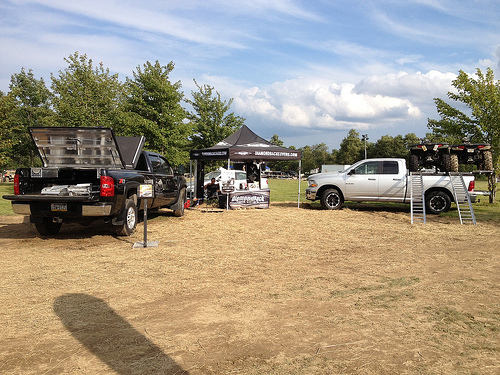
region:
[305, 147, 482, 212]
Silver four wheeled pick up truck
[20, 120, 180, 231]
Black pick up truck parked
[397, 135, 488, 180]
Two four wheeler ATVs in bed of a pickup truck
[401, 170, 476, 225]
Two ladders leaning against silver truck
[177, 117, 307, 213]
Black and white tent over a table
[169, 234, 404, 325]
Patchy brown dirt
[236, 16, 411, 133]
Pale blue sky with large clouds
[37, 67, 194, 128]
Stand of green trees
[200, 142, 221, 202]
Man sitting down under tent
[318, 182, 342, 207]
Wheel of a truck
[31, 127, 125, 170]
Open bed of truck.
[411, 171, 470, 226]
A ramp for the truck.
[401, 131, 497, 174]
A pair of ATVs.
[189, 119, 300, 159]
The black tent roof.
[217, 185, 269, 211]
A booth with advertisements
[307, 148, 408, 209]
The cab of a truck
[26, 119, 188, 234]
A black ford truck.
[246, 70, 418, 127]
The clouds in the sky.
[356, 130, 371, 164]
A light in the distance.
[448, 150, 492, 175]
Wheels covered in dirt.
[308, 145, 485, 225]
a silver pickup truck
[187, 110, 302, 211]
a black tent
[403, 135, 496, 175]
two four wheelers on top of a truck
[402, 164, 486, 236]
two metal ramps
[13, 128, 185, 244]
a black pick up truck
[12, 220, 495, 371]
dirt ground behind a pickup truck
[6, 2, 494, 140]
a gorgeous cloudy blue sky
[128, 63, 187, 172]
a leafy green tree in front of a truck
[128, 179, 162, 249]
a black display sign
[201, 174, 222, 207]
a person sitting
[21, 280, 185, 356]
the shadow is on the ground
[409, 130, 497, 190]
the four wheelers are on the truck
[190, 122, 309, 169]
the tent is black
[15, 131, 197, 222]
the truck is black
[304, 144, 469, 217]
the truck is silver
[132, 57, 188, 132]
the tree is small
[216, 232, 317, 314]
the dirt is brown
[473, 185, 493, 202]
the tailgate is down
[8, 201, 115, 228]
the bumper is shiney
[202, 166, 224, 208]
the man is sitting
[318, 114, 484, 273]
the car is white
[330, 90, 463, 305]
the car is white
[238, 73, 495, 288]
the car is white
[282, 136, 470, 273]
the car is white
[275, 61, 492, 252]
the car is white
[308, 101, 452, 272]
the car is white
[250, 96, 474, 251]
the car is white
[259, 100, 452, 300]
the car is white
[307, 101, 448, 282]
the car is white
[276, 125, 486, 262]
the car is white